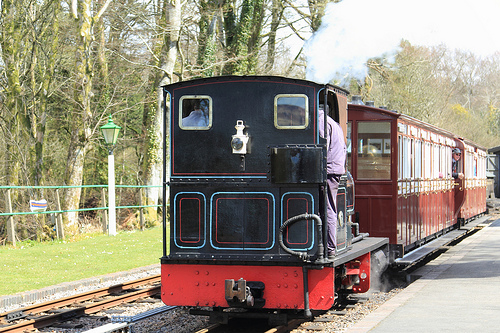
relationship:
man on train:
[299, 98, 356, 267] [131, 68, 500, 317]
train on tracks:
[131, 68, 500, 317] [10, 294, 160, 332]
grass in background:
[7, 241, 138, 277] [5, 71, 148, 265]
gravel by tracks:
[146, 319, 196, 330] [10, 294, 160, 332]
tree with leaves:
[203, 8, 255, 69] [237, 11, 251, 68]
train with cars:
[131, 68, 500, 317] [345, 87, 499, 284]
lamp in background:
[91, 105, 138, 238] [5, 71, 148, 265]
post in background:
[95, 111, 123, 239] [5, 71, 148, 265]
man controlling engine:
[299, 98, 356, 267] [131, 68, 500, 317]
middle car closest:
[345, 87, 499, 284] [106, 57, 475, 324]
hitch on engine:
[215, 264, 257, 314] [131, 68, 500, 317]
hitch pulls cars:
[215, 264, 257, 314] [345, 87, 499, 284]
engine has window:
[131, 68, 500, 317] [175, 88, 214, 138]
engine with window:
[131, 68, 500, 317] [175, 88, 214, 138]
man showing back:
[299, 98, 356, 267] [310, 109, 352, 182]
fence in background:
[9, 178, 94, 245] [5, 71, 148, 265]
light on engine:
[227, 116, 259, 159] [131, 68, 500, 317]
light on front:
[227, 116, 259, 159] [167, 82, 322, 278]